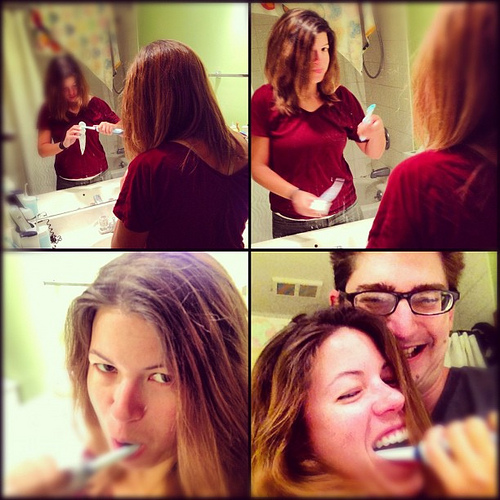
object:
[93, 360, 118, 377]
eyes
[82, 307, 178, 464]
face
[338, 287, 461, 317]
glasses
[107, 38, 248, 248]
girl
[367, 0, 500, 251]
girl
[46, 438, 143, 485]
toothbrush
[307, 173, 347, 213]
toothpaste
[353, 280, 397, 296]
eyebrow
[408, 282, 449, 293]
eyebrow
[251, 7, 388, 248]
person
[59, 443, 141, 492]
brush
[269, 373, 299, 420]
blonde streaks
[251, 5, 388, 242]
girl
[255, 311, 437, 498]
girl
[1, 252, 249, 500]
girl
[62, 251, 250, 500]
hair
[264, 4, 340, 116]
hair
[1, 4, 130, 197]
mirror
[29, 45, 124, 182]
reflection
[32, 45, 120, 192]
girl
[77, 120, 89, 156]
toothpaste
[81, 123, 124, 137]
toothbrush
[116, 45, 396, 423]
photo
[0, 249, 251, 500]
person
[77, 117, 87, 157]
tube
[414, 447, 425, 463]
blue floor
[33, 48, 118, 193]
person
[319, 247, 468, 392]
man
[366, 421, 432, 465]
mouth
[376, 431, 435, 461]
toothbrush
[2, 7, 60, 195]
shower curtain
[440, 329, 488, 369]
shower curtain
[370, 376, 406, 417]
nose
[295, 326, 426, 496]
face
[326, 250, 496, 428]
person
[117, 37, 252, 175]
brown hair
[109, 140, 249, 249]
shirt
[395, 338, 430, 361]
smile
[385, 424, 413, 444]
teeth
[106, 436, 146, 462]
mouth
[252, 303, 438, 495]
hair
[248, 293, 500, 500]
person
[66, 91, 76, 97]
teeth